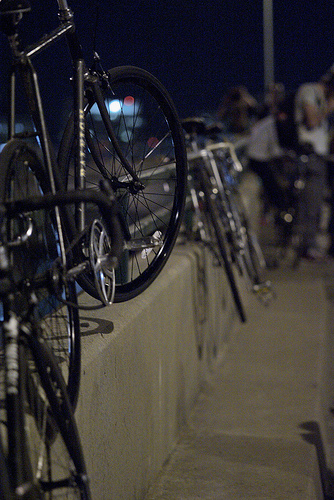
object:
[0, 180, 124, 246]
handles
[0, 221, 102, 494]
bike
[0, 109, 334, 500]
bridge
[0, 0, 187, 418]
bicycles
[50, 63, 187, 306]
front tire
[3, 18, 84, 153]
frame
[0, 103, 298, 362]
bridge's ramp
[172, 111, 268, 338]
bike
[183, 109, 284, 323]
bike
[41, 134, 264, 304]
ramp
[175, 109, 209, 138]
seat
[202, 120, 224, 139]
seat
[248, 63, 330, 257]
people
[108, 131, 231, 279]
railing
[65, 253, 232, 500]
wall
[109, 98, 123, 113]
lights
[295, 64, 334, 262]
man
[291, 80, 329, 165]
shirt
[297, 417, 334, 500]
shadow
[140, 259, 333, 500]
ground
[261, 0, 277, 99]
light post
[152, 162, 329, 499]
sidewalk